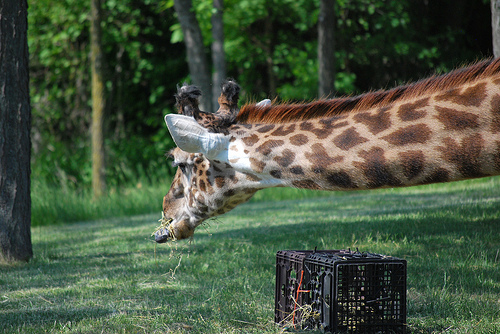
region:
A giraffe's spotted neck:
[252, 47, 497, 203]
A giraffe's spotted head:
[142, 67, 273, 252]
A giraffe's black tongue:
[149, 231, 173, 244]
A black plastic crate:
[261, 239, 426, 332]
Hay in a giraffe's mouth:
[145, 195, 183, 257]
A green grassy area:
[58, 268, 266, 324]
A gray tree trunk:
[1, 6, 35, 275]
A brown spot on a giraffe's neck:
[326, 119, 370, 151]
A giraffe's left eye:
[168, 153, 195, 176]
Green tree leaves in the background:
[224, 5, 256, 59]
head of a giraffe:
[147, 80, 252, 256]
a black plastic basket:
[270, 246, 410, 332]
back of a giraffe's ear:
[162, 110, 225, 162]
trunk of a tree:
[1, 0, 33, 263]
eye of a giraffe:
[173, 154, 187, 171]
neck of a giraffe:
[232, 63, 499, 188]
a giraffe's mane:
[240, 60, 497, 127]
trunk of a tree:
[87, 2, 108, 199]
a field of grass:
[0, 180, 498, 332]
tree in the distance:
[173, 0, 222, 111]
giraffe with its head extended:
[133, 57, 498, 232]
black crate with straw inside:
[260, 246, 404, 331]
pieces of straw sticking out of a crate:
[279, 283, 342, 324]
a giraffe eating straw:
[134, 85, 278, 277]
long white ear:
[162, 109, 230, 167]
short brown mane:
[234, 49, 493, 125]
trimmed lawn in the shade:
[37, 174, 482, 327]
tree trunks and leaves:
[46, 2, 386, 222]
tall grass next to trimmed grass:
[34, 160, 174, 220]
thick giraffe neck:
[236, 88, 498, 178]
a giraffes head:
[42, 8, 493, 290]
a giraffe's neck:
[67, 48, 497, 255]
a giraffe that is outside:
[64, 33, 492, 304]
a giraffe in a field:
[67, 50, 454, 332]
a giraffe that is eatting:
[26, 32, 498, 279]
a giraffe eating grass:
[134, 38, 492, 330]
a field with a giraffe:
[17, 33, 489, 319]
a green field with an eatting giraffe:
[37, 3, 499, 265]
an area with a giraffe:
[46, 58, 499, 322]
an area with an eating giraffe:
[64, 43, 486, 329]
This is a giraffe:
[61, 46, 498, 239]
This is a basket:
[258, 228, 431, 333]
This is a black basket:
[268, 233, 410, 325]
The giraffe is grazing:
[113, 112, 283, 278]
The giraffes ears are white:
[167, 117, 229, 164]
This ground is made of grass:
[71, 215, 211, 328]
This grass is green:
[38, 251, 179, 332]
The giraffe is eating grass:
[149, 195, 208, 252]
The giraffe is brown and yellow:
[232, 120, 479, 173]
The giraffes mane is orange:
[262, 84, 477, 117]